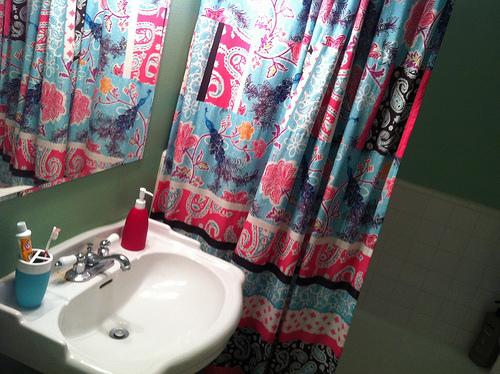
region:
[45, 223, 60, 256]
A white toothbrush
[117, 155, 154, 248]
A red hand wash bottle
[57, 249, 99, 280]
A silver water tap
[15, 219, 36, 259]
An orange and white tootpaste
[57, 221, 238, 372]
A white bathroom sink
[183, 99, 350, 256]
A flower pattern curtain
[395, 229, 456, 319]
A tile white bathroom wall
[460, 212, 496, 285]
A tile white bathroom wall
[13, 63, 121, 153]
A bathroom clear mirror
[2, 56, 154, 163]
A reflection of the curtain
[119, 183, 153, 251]
pink soap dispencer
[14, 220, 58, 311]
blue toothbrush holder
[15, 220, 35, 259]
holds toothpaste in back of holder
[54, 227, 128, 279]
sink faucet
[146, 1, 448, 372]
pink and blue themed shower curtain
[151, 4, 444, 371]
fancy print on shower curtain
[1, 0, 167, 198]
reflection of shower curtain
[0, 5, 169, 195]
mirror hanging above bathroom sink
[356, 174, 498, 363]
tiles on shower wall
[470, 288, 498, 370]
black bottle of liquid in bathtub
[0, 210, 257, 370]
A small white sink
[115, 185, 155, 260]
A hand soap dispenser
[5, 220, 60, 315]
A blue toothbrush holder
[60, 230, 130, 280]
A chrome bathroom faucet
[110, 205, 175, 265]
A red dispenser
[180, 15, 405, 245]
A printed shower curtain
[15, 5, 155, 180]
A mirror over sink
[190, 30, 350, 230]
A red, blue and black curtain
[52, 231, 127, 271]
A chrome faucet with white handles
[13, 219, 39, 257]
A tube of red and white toothpaste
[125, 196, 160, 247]
Red soap dispenser on sink.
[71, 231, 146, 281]
Silver faucet on sink.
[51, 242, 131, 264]
White handles on sink faucet.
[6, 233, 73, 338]
Blue cup on side of sink.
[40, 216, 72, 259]
Toothbrush in blue cup.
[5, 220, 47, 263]
Toothpaste in blue cup.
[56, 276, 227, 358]
Bowl of sink is white.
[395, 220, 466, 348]
White tiles on lower half of wall near tub.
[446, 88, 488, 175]
Upper section of bathroom wall is green.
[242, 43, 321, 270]
Colorful shower curtain in bathroom.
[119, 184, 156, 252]
Hand soap in a bottle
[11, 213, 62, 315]
Toothbrush in a cup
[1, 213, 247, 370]
A faucet and sink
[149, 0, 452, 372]
A colorful shower curtain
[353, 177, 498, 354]
White tiles on the wall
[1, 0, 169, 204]
A mirror on the wall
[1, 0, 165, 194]
Shower curtain's reflection in the mirror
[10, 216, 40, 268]
White and yellow toothpaste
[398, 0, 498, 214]
The wall is green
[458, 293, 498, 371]
Shampoo bottle on bathtub